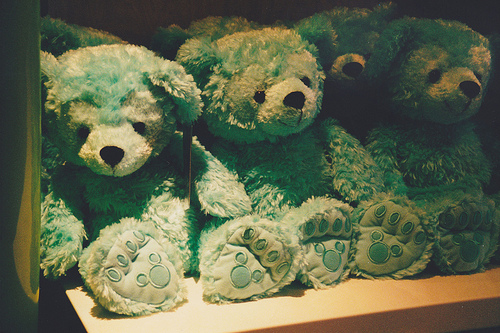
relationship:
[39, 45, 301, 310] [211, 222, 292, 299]
bear has paw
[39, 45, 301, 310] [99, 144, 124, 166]
bear has nose